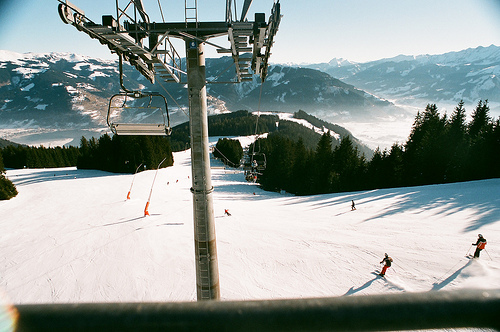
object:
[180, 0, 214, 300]
ladder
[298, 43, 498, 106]
mountains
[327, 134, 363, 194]
trees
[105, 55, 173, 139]
seat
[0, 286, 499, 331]
pole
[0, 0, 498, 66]
blue sky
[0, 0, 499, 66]
white clouds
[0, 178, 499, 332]
hill side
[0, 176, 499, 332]
snow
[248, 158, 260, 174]
person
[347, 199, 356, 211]
person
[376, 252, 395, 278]
people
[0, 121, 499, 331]
slope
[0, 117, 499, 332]
hill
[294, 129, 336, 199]
trees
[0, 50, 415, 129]
hill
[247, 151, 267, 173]
ski lift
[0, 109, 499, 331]
ground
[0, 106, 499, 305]
ice